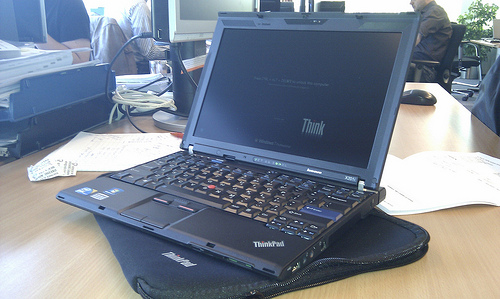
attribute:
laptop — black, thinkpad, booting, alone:
[204, 51, 338, 250]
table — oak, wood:
[28, 231, 66, 260]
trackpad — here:
[141, 188, 180, 227]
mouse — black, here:
[386, 83, 445, 108]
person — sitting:
[90, 11, 116, 56]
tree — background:
[447, 1, 499, 39]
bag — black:
[36, 103, 98, 145]